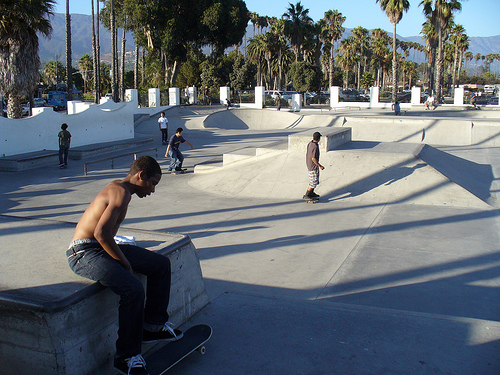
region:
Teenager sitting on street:
[48, 155, 234, 374]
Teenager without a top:
[53, 152, 236, 373]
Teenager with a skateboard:
[58, 148, 220, 373]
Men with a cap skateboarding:
[294, 119, 329, 209]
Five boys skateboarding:
[9, 73, 403, 373]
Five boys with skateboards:
[5, 42, 485, 373]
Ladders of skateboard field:
[187, 133, 295, 173]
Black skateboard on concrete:
[103, 312, 219, 372]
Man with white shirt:
[155, 105, 177, 146]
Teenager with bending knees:
[163, 123, 199, 173]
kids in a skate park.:
[56, 111, 321, 373]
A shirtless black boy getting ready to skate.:
[68, 157, 217, 373]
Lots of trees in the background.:
[2, 0, 498, 114]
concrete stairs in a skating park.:
[191, 126, 351, 176]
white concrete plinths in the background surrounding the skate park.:
[0, 85, 475, 159]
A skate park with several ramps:
[0, 107, 497, 324]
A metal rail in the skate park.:
[79, 146, 162, 176]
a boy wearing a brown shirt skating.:
[305, 129, 325, 207]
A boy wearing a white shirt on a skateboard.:
[154, 107, 172, 145]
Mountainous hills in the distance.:
[20, 11, 498, 80]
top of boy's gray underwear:
[73, 237, 96, 244]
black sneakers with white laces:
[150, 318, 195, 340]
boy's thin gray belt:
[59, 250, 96, 259]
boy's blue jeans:
[57, 245, 182, 324]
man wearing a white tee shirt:
[153, 112, 179, 133]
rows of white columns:
[225, 87, 475, 119]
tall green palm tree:
[372, 2, 428, 109]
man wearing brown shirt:
[290, 135, 334, 177]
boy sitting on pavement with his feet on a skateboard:
[80, 150, 240, 347]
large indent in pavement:
[203, 109, 316, 144]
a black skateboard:
[134, 323, 239, 369]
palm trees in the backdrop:
[384, 5, 456, 96]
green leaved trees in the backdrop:
[132, 8, 239, 97]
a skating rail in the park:
[82, 152, 169, 171]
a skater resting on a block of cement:
[75, 155, 201, 355]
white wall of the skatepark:
[10, 106, 151, 153]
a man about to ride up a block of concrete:
[300, 132, 339, 206]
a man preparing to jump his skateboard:
[165, 126, 197, 180]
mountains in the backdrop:
[44, 17, 489, 82]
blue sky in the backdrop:
[247, 3, 494, 39]